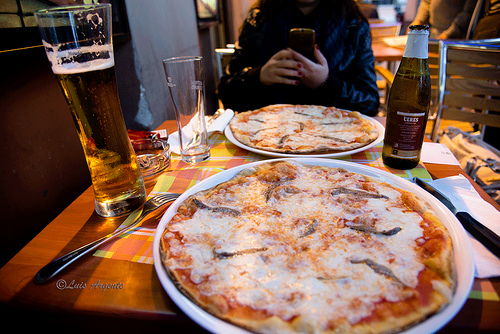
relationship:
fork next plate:
[31, 192, 180, 285] [166, 136, 471, 326]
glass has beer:
[32, 2, 145, 216] [45, 41, 143, 204]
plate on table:
[336, 139, 350, 157] [3, 114, 497, 332]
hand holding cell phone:
[261, 46, 297, 87] [288, 27, 315, 63]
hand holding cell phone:
[293, 49, 329, 85] [288, 27, 315, 63]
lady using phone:
[216, 0, 379, 116] [276, 52, 349, 94]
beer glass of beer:
[160, 55, 211, 163] [52, 65, 142, 196]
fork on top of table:
[31, 192, 180, 285] [10, 85, 498, 322]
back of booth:
[5, 50, 94, 263] [1, 1, 102, 268]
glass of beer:
[32, 0, 150, 219] [51, 54, 148, 201]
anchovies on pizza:
[355, 255, 415, 294] [254, 196, 357, 271]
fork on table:
[33, 190, 179, 288] [7, 152, 164, 326]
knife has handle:
[411, 176, 499, 258] [459, 207, 498, 252]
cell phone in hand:
[282, 22, 317, 67] [285, 38, 335, 83]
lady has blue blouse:
[216, 0, 379, 116] [217, 2, 380, 117]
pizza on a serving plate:
[159, 160, 456, 332] [153, 159, 473, 333]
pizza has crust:
[159, 160, 456, 332] [427, 218, 454, 303]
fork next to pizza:
[33, 190, 179, 288] [159, 160, 456, 332]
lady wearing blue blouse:
[229, 22, 381, 108] [233, 4, 385, 119]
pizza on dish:
[159, 160, 456, 332] [150, 155, 477, 332]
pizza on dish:
[229, 103, 380, 154] [223, 104, 383, 159]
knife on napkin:
[415, 171, 498, 248] [430, 162, 499, 229]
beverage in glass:
[42, 45, 145, 201] [32, 0, 150, 219]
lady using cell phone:
[216, 0, 379, 116] [287, 23, 327, 64]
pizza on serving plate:
[159, 160, 456, 332] [152, 156, 474, 333]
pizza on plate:
[229, 103, 380, 154] [219, 108, 384, 158]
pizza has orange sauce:
[159, 160, 456, 332] [371, 302, 410, 319]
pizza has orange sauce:
[229, 98, 378, 150] [371, 302, 410, 319]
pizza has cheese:
[159, 160, 456, 332] [184, 172, 422, 322]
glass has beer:
[32, 0, 150, 219] [52, 65, 142, 196]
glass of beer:
[32, 0, 150, 219] [52, 65, 142, 196]